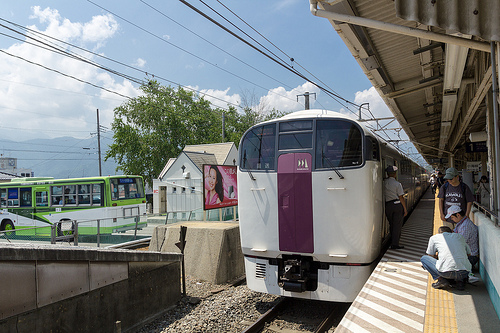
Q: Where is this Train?
A: Station.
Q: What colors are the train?
A: White and purple.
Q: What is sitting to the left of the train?
A: A bus.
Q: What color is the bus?
A: Green and white.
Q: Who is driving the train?
A: The conductor.